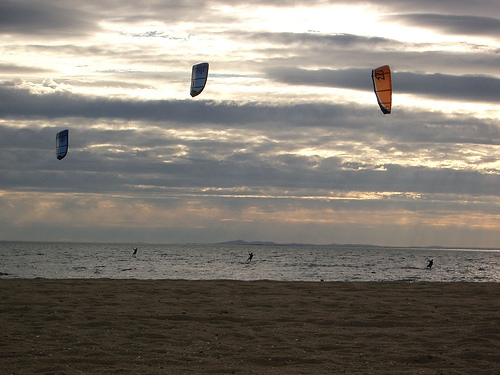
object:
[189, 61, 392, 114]
two sails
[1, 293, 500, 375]
footprints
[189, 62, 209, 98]
kite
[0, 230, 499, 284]
horizon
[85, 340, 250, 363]
dots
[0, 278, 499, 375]
sand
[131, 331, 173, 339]
pit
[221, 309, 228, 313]
pit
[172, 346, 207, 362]
pit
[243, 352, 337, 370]
pit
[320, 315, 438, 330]
pit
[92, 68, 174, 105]
light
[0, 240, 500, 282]
ocean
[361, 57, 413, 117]
right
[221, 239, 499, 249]
land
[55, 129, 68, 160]
kite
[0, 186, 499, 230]
orange light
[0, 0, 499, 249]
sky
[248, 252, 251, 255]
arm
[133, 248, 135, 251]
arm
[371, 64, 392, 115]
kite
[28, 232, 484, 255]
distance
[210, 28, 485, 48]
cloud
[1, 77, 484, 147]
cloud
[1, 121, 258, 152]
cloud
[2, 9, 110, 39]
cloud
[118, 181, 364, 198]
cloud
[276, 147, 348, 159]
sunlight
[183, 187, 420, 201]
sunlight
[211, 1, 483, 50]
sunlight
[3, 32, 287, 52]
sunlight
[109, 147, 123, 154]
sunlight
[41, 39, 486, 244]
air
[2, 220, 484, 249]
streak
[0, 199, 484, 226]
streak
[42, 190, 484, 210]
streak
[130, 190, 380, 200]
streak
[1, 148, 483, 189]
streak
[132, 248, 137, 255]
figure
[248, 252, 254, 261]
figure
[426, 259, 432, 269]
figure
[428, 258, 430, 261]
arm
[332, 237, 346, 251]
bad sentence